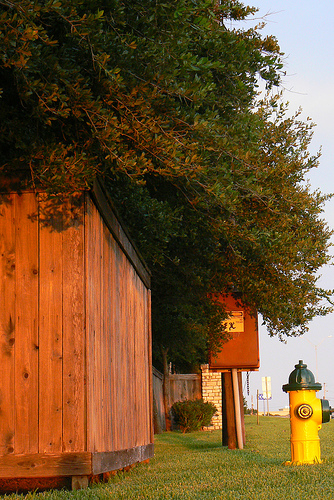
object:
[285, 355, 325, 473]
hydrant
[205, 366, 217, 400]
pillar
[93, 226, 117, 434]
fence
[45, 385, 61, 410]
wood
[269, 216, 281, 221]
leaf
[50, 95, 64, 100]
leaf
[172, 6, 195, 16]
leaf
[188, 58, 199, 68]
leaf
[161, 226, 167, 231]
leaf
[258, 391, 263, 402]
sign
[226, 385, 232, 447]
post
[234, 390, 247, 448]
pole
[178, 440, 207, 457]
ground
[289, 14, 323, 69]
sky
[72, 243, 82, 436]
panel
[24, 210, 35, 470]
panel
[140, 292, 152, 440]
panel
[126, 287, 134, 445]
panel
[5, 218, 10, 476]
panel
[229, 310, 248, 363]
power box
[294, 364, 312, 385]
top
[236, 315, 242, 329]
sticker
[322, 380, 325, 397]
pole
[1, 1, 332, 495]
photo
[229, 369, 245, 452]
wooden post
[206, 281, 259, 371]
metal sign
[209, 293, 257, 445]
sign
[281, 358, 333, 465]
fire hydrant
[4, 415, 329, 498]
grass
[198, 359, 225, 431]
column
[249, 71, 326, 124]
clouds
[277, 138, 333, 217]
clouds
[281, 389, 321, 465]
yellow base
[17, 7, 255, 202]
tree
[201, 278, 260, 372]
box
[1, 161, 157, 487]
building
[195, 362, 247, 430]
brick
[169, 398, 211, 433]
bush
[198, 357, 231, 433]
structure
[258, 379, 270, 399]
signs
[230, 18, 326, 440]
sky